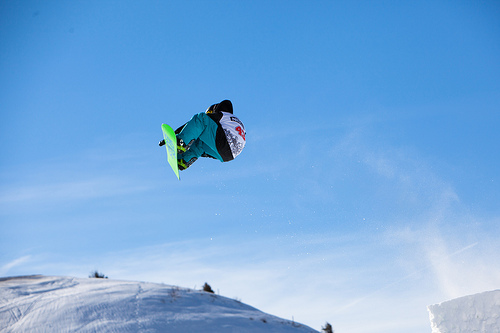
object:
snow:
[0, 273, 327, 332]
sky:
[1, 1, 155, 135]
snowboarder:
[162, 99, 246, 179]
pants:
[174, 111, 226, 168]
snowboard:
[158, 123, 180, 178]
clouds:
[0, 120, 499, 332]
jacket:
[213, 109, 248, 161]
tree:
[198, 283, 216, 294]